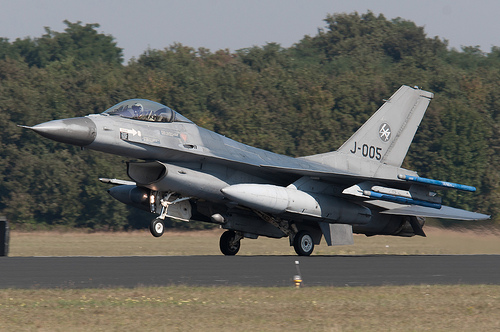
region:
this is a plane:
[164, 94, 307, 259]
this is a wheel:
[281, 248, 328, 282]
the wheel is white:
[294, 240, 317, 255]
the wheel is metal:
[283, 219, 376, 321]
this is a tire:
[292, 221, 312, 272]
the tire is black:
[286, 242, 323, 274]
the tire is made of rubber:
[267, 213, 354, 318]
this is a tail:
[314, 112, 463, 194]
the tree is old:
[326, 79, 343, 120]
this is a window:
[112, 86, 193, 166]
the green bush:
[238, 64, 337, 134]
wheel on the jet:
[216, 231, 241, 256]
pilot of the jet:
[128, 99, 144, 118]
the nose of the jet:
[11, 119, 45, 132]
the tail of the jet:
[391, 87, 430, 145]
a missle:
[221, 185, 270, 206]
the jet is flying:
[6, 83, 491, 241]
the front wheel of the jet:
[151, 219, 168, 236]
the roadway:
[355, 254, 460, 276]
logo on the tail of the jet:
[376, 120, 400, 141]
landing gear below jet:
[146, 187, 198, 239]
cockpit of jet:
[216, 179, 416, 248]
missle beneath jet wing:
[216, 182, 431, 244]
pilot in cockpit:
[130, 99, 150, 121]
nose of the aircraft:
[13, 117, 108, 144]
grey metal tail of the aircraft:
[338, 80, 428, 171]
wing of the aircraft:
[225, 155, 487, 195]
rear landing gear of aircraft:
[215, 221, 325, 252]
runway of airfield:
[20, 251, 450, 286]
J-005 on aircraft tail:
[346, 139, 390, 164]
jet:
[27, 88, 461, 235]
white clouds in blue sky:
[151, 7, 203, 41]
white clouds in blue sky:
[193, 11, 271, 52]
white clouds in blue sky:
[417, 14, 451, 29]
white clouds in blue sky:
[441, 6, 483, 36]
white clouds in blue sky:
[21, 6, 61, 24]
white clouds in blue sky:
[237, 8, 285, 58]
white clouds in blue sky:
[109, 17, 153, 58]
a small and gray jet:
[22, 45, 493, 327]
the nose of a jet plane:
[20, 91, 108, 163]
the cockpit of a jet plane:
[104, 78, 175, 135]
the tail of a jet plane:
[310, 79, 460, 176]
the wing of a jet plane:
[267, 153, 479, 208]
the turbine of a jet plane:
[224, 165, 338, 222]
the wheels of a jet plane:
[131, 203, 321, 264]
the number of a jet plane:
[338, 138, 392, 160]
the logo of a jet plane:
[374, 125, 406, 140]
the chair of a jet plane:
[135, 103, 173, 125]